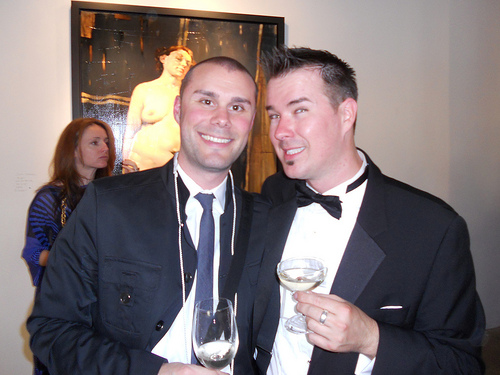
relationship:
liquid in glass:
[194, 339, 235, 369] [194, 297, 241, 371]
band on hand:
[319, 309, 329, 325] [292, 288, 381, 360]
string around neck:
[173, 151, 238, 307] [178, 147, 229, 189]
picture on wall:
[70, 1, 285, 194] [0, 1, 499, 375]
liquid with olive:
[275, 267, 325, 292] [295, 276, 306, 282]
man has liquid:
[251, 45, 488, 375] [275, 267, 325, 292]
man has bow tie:
[251, 45, 488, 375] [295, 182, 342, 219]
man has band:
[27, 56, 265, 374] [319, 309, 329, 325]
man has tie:
[27, 56, 265, 374] [194, 191, 217, 366]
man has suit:
[251, 45, 488, 375] [251, 146, 487, 374]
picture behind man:
[70, 1, 285, 194] [251, 45, 488, 375]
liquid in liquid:
[280, 269, 322, 293] [275, 267, 325, 292]